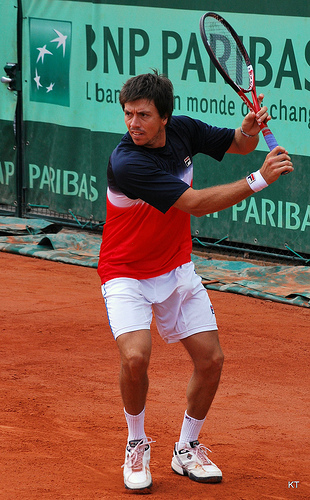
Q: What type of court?
A: Clay.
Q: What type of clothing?
A: Shorts.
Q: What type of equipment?
A: Racket.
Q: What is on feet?
A: Shoes.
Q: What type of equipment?
A: Racket.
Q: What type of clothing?
A: Shorts.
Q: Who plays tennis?
A: The man.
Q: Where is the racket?
A: In the man's hands.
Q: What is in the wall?
A: Advertising.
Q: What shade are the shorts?
A: White.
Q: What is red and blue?
A: The shirt.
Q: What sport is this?
A: Tennis.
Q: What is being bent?
A: The man's legs.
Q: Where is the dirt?
A: On the ground.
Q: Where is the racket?
A: In the man's hands.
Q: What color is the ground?
A: Brown.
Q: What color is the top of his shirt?
A: Blue.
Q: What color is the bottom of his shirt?
A: Red.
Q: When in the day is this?
A: When it's daylight.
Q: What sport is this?
A: Tennis.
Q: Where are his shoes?
A: On his feet.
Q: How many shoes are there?
A: Two.